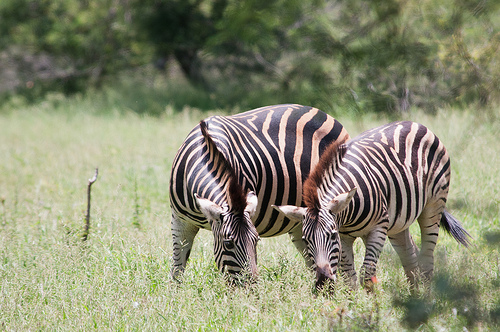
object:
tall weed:
[82, 165, 99, 239]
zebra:
[169, 101, 346, 294]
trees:
[0, 0, 499, 112]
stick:
[78, 167, 104, 241]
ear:
[192, 191, 224, 221]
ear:
[244, 189, 259, 213]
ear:
[270, 201, 305, 223]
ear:
[328, 185, 358, 218]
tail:
[440, 206, 476, 250]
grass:
[1, 114, 176, 329]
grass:
[167, 239, 489, 329]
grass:
[434, 108, 495, 324]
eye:
[222, 239, 236, 249]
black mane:
[196, 118, 245, 216]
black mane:
[300, 138, 342, 220]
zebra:
[270, 119, 472, 301]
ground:
[1, 98, 500, 331]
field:
[7, 0, 499, 332]